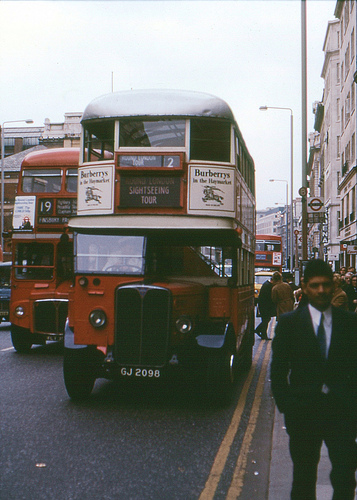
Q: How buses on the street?
A: Three.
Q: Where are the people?
A: At the sidewalk.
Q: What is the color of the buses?
A: Red.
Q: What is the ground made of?
A: Gravel and cement.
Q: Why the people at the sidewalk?
A: Walking.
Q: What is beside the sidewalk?
A: Buildings.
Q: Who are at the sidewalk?
A: People.